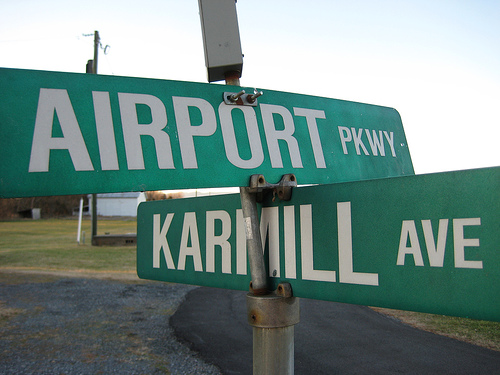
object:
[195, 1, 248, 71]
box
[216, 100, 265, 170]
letter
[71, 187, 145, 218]
building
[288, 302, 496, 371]
road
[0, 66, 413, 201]
sign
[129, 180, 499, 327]
sign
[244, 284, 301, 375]
pole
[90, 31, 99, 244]
pole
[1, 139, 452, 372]
street signs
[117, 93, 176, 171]
letter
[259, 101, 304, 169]
letter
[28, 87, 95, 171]
letter a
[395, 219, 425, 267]
letter a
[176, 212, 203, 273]
letter a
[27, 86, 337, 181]
lettering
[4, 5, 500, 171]
sky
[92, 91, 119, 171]
letter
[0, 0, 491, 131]
background